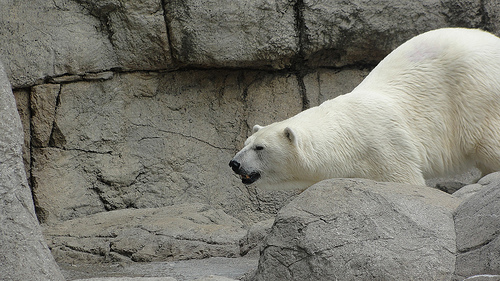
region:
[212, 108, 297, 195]
head of a polar bear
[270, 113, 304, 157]
ear of a polar bear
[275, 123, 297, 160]
an ear of a polar bear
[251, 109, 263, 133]
ear of a polar bear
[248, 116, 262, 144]
an ear of a polar bear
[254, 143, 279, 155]
eye of a polar bear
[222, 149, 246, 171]
nose of a polar bear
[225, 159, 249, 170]
a nose of a polar bear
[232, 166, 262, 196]
mouth of a polar bear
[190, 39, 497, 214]
the bear is white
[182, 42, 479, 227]
the bear is white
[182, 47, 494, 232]
the bear is white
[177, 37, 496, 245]
a white polar bear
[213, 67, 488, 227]
a white polar bear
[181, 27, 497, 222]
a white polar bear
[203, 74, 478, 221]
a white polar bear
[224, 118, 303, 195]
Head of a polar bear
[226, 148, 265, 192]
Open mouth of a polar bear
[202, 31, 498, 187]
Full body of a polar bear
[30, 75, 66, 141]
Crack in the rock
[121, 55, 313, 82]
shadow of overhanging rock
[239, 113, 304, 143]
Two ears of a polar bear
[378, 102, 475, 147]
Soft white fur of a polar bear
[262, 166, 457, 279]
round rock in front of a polar bear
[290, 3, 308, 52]
Black crack line of a rock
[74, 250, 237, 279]
Floor of the pen of a polar bear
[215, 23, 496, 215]
A polar bear on a rock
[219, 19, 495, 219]
A polar bear on a rock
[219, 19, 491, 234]
A polar bear on a rock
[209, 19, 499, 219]
A polar bear on a rock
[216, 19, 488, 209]
A polar bear on a rock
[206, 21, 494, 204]
A polar bear on a rock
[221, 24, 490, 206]
A polar bear on a rock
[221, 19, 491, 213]
A polar bear on a rock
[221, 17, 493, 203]
A polar bear on a rock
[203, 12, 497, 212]
a polar bear in a zoo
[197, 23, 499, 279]
a polar bear among rocks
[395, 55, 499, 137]
fur on a polar bear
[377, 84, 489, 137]
white fur on a polar bear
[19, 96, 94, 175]
cracks in the rocks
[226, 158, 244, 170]
nose on a polar bear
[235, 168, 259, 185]
mouth of a polar bear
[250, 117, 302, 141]
ears of a polar bear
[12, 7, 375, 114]
rocks on top of rocks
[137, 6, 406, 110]
lines in the rocks